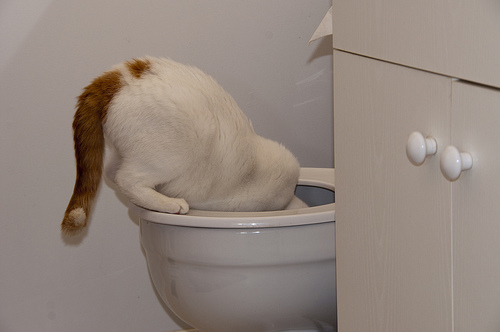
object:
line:
[446, 182, 456, 332]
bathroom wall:
[1, 2, 330, 330]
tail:
[55, 69, 124, 234]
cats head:
[288, 197, 312, 212]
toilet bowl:
[125, 166, 335, 332]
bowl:
[139, 166, 347, 329]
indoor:
[3, 0, 500, 332]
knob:
[437, 146, 474, 183]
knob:
[405, 131, 438, 167]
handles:
[405, 130, 473, 182]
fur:
[104, 61, 260, 182]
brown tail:
[60, 70, 117, 248]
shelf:
[327, 1, 498, 332]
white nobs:
[404, 130, 473, 182]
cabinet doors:
[333, 52, 498, 332]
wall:
[3, 4, 333, 330]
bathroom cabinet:
[332, 0, 498, 331]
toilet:
[138, 164, 339, 332]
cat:
[53, 54, 302, 247]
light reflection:
[236, 221, 260, 234]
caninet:
[334, 0, 497, 332]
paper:
[302, 3, 337, 47]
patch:
[121, 56, 152, 79]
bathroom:
[0, 0, 499, 331]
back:
[124, 54, 254, 137]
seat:
[128, 166, 334, 227]